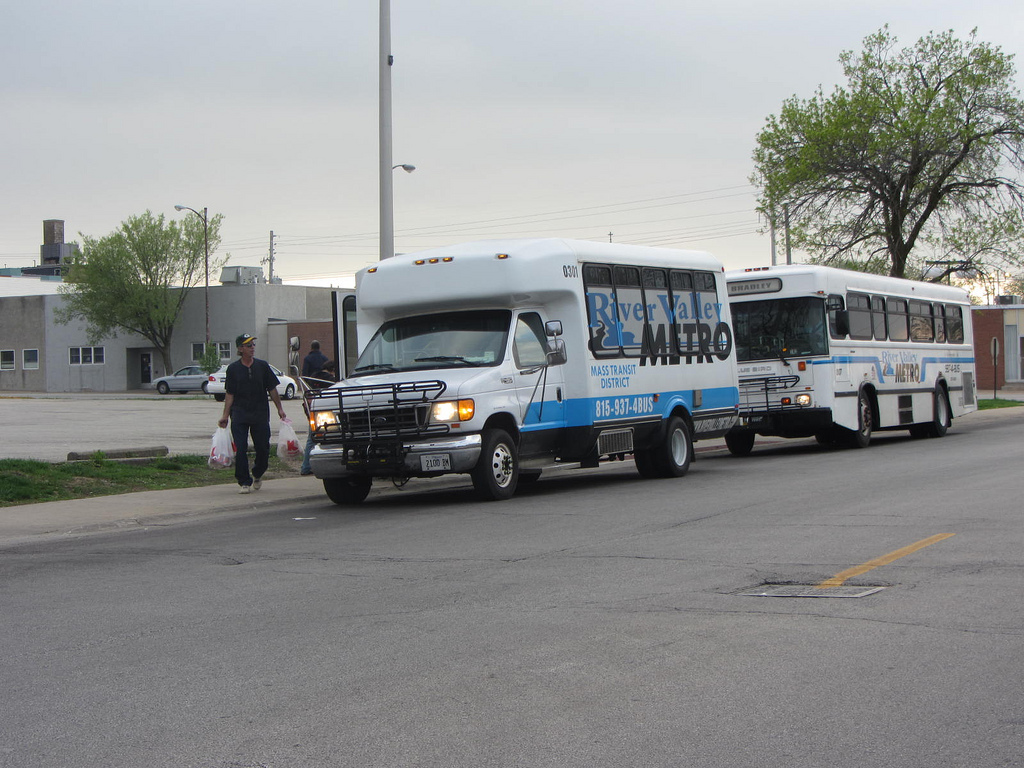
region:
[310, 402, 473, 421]
the white track has its headlights on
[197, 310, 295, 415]
A man wearing a cap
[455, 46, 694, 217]
The sky is overcast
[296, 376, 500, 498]
Headlights are turned on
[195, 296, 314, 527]
A man is holding two plastic bags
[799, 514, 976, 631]
A yellow line on the street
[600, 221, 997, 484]
A bus behind a truck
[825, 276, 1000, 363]
Windows on the side of a bus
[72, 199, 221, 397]
A small tree next to a building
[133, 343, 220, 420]
A parked silver car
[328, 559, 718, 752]
A street pavement is gray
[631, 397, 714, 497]
A black tire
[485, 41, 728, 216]
The sky appears overcast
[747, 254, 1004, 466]
A white bus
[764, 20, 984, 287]
A tree with green leaves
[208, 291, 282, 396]
A man is wearing a hat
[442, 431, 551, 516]
A black tire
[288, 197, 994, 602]
A bus is behind another vehicle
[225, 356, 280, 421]
the shirt is black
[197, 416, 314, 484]
the bags are white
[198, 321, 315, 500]
the man is carrying two bags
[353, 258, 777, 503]
the truck is white and blue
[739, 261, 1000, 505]
the bus is white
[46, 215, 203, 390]
the tree in front of the building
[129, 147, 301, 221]
the sky is gray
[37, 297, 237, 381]
the building is gray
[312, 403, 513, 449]
the headlights are on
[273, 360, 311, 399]
the car is white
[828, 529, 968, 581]
yellow stripe on a street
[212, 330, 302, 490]
a man holding two shopping bags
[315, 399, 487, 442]
illuminated headlights on a vehicle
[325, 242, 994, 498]
two transportation vehicles parked near each other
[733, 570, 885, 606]
sewer access on a road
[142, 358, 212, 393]
a car parked outside a building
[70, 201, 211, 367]
large tree in front of a building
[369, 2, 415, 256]
a streetlight behind a vehicle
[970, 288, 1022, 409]
a building behind a bus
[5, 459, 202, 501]
grass next to a sidewalk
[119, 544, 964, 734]
black paved road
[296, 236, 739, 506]
a blue and white bus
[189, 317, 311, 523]
a man carrying shopping bags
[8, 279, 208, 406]
a gray building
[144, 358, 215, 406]
a parked gray car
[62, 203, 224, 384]
a tree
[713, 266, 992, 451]
a city bus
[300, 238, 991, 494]
two buses parked on the side of the street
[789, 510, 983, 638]
a yellow center line on the street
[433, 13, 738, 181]
overcast sky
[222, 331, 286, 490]
a man dressed in black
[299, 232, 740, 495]
a large passenger van parked by the curb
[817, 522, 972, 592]
a yellow stripe on the street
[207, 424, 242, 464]
a plastic bag in the man's hand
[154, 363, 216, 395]
a car parked by the building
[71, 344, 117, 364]
a set of three windows in the building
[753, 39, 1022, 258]
a tree behind the second vehicle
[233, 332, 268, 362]
the man's head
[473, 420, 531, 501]
a front tire on the van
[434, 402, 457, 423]
a headlight on the van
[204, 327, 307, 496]
man walking and holding plastic bags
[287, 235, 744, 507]
a metro bus with lights on